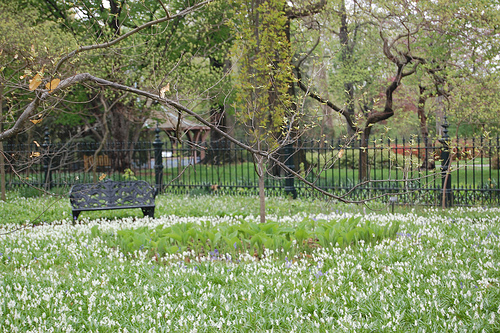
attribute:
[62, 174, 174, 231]
park bench — black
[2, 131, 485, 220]
fence — black, metal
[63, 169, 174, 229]
bench — metal, green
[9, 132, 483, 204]
fence — long, metal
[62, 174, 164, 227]
bench — black, metal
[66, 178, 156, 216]
bench — green, metal